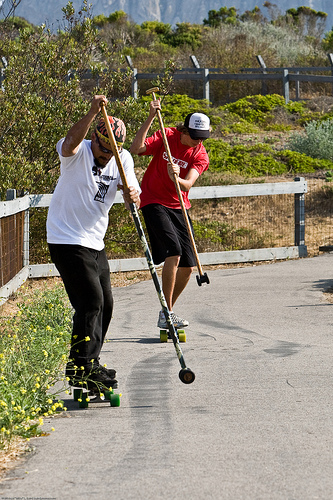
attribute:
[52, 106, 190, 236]
player — in the picture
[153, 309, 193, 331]
shoes — in the picture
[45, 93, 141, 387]
man — in the picture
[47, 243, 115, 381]
black pants — in the picture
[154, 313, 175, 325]
white shoes — in the picture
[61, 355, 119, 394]
shoes — in the picture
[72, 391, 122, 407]
wheels — in the picture